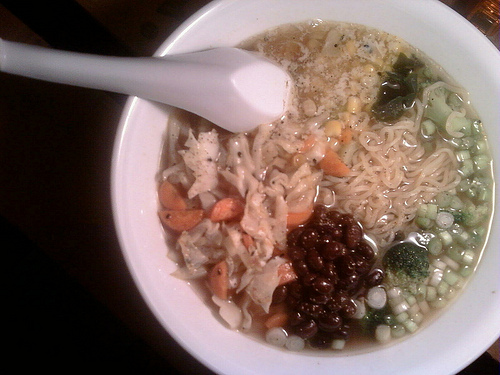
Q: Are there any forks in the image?
A: No, there are no forks.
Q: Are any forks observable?
A: No, there are no forks.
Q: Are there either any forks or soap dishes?
A: No, there are no forks or soap dishes.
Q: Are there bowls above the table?
A: Yes, there is a bowl above the table.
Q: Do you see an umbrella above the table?
A: No, there is a bowl above the table.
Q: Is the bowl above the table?
A: Yes, the bowl is above the table.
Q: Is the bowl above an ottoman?
A: No, the bowl is above the table.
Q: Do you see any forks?
A: No, there are no forks.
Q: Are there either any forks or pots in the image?
A: No, there are no forks or pots.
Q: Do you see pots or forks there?
A: No, there are no forks or pots.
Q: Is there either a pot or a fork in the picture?
A: No, there are no forks or pots.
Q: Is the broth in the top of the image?
A: Yes, the broth is in the top of the image.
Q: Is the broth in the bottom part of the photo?
A: No, the broth is in the top of the image.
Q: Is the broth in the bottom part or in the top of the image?
A: The broth is in the top of the image.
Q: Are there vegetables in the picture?
A: Yes, there are vegetables.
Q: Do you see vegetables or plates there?
A: Yes, there are vegetables.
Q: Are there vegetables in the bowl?
A: Yes, there are vegetables in the bowl.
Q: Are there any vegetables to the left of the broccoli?
A: Yes, there are vegetables to the left of the broccoli.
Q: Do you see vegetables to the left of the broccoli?
A: Yes, there are vegetables to the left of the broccoli.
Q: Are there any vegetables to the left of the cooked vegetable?
A: Yes, there are vegetables to the left of the broccoli.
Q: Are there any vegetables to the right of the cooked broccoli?
A: No, the vegetables are to the left of the broccoli.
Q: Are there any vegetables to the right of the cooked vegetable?
A: No, the vegetables are to the left of the broccoli.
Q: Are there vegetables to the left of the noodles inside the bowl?
A: Yes, there are vegetables to the left of the noodles.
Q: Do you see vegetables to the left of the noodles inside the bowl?
A: Yes, there are vegetables to the left of the noodles.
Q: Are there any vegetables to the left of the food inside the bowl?
A: Yes, there are vegetables to the left of the noodles.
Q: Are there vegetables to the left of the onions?
A: Yes, there are vegetables to the left of the onions.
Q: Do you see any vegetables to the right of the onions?
A: No, the vegetables are to the left of the onions.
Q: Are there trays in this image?
A: No, there are no trays.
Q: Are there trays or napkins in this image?
A: No, there are no trays or napkins.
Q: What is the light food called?
A: The food is Chinese food.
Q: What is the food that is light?
A: The food is Chinese food.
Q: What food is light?
A: The food is Chinese food.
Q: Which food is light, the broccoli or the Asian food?
A: The Asian food is light.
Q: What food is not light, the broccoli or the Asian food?
A: The broccoli is not light.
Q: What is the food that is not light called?
A: The food is broccoli.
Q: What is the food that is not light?
A: The food is broccoli.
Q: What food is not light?
A: The food is broccoli.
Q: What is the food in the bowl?
A: The food is Chinese food.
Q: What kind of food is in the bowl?
A: The food is Chinese food.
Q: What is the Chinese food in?
A: The Chinese food is in the bowl.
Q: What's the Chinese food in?
A: The Chinese food is in the bowl.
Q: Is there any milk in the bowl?
A: No, there is Chinese food in the bowl.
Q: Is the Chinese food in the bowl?
A: Yes, the Chinese food is in the bowl.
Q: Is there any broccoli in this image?
A: Yes, there is broccoli.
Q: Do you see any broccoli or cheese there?
A: Yes, there is broccoli.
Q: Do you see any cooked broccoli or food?
A: Yes, there is cooked broccoli.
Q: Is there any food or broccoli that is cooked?
A: Yes, the broccoli is cooked.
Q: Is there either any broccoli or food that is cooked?
A: Yes, the broccoli is cooked.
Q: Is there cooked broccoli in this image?
A: Yes, there is cooked broccoli.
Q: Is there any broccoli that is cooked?
A: Yes, there is broccoli that is cooked.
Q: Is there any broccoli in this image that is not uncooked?
A: Yes, there is cooked broccoli.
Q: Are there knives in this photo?
A: No, there are no knives.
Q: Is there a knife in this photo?
A: No, there are no knives.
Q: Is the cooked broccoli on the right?
A: Yes, the broccoli is on the right of the image.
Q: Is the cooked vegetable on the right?
A: Yes, the broccoli is on the right of the image.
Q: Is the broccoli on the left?
A: No, the broccoli is on the right of the image.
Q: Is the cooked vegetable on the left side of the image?
A: No, the broccoli is on the right of the image.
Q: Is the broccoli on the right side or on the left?
A: The broccoli is on the right of the image.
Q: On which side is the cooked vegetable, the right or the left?
A: The broccoli is on the right of the image.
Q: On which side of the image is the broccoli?
A: The broccoli is on the right of the image.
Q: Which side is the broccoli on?
A: The broccoli is on the right of the image.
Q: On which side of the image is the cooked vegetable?
A: The broccoli is on the right of the image.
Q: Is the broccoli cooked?
A: Yes, the broccoli is cooked.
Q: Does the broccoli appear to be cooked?
A: Yes, the broccoli is cooked.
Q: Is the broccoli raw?
A: No, the broccoli is cooked.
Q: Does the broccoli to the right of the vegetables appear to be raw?
A: No, the broccoli is cooked.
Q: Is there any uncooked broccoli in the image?
A: No, there is broccoli but it is cooked.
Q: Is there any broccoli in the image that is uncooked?
A: No, there is broccoli but it is cooked.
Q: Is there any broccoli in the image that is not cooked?
A: No, there is broccoli but it is cooked.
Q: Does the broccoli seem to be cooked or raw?
A: The broccoli is cooked.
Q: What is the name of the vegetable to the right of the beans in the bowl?
A: The vegetable is broccoli.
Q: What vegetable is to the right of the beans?
A: The vegetable is broccoli.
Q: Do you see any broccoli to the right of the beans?
A: Yes, there is broccoli to the right of the beans.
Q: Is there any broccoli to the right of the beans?
A: Yes, there is broccoli to the right of the beans.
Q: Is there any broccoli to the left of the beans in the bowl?
A: No, the broccoli is to the right of the beans.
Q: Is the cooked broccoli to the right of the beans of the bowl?
A: Yes, the broccoli is to the right of the beans.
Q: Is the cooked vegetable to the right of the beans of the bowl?
A: Yes, the broccoli is to the right of the beans.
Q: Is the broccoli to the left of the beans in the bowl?
A: No, the broccoli is to the right of the beans.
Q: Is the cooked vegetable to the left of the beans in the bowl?
A: No, the broccoli is to the right of the beans.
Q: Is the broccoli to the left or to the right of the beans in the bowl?
A: The broccoli is to the right of the beans.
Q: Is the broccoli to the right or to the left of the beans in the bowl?
A: The broccoli is to the right of the beans.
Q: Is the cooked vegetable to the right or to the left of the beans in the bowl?
A: The broccoli is to the right of the beans.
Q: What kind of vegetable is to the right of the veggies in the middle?
A: The vegetable is broccoli.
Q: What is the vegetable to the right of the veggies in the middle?
A: The vegetable is broccoli.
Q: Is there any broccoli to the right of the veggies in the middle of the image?
A: Yes, there is broccoli to the right of the vegetables.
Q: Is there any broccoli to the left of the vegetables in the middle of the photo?
A: No, the broccoli is to the right of the veggies.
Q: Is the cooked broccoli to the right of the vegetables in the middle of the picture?
A: Yes, the broccoli is to the right of the vegetables.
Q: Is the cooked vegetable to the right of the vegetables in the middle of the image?
A: Yes, the broccoli is to the right of the vegetables.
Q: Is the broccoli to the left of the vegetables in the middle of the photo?
A: No, the broccoli is to the right of the vegetables.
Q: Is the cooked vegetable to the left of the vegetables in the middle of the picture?
A: No, the broccoli is to the right of the vegetables.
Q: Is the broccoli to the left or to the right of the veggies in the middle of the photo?
A: The broccoli is to the right of the veggies.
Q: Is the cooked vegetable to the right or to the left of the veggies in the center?
A: The broccoli is to the right of the veggies.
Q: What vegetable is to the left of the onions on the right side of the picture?
A: The vegetable is broccoli.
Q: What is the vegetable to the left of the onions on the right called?
A: The vegetable is broccoli.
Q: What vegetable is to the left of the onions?
A: The vegetable is broccoli.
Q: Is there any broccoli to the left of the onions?
A: Yes, there is broccoli to the left of the onions.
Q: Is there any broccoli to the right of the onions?
A: No, the broccoli is to the left of the onions.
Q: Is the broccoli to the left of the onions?
A: Yes, the broccoli is to the left of the onions.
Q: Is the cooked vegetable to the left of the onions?
A: Yes, the broccoli is to the left of the onions.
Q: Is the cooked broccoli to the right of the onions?
A: No, the broccoli is to the left of the onions.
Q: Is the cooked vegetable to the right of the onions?
A: No, the broccoli is to the left of the onions.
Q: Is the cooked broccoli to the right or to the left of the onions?
A: The broccoli is to the left of the onions.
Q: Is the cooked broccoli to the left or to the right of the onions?
A: The broccoli is to the left of the onions.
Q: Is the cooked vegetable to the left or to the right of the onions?
A: The broccoli is to the left of the onions.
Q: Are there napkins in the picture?
A: No, there are no napkins.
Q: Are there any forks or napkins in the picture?
A: No, there are no napkins or forks.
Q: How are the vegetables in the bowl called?
A: The vegetables are beans.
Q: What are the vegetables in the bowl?
A: The vegetables are beans.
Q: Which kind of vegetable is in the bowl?
A: The vegetables are beans.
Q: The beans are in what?
A: The beans are in the bowl.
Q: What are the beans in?
A: The beans are in the bowl.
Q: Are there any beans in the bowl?
A: Yes, there are beans in the bowl.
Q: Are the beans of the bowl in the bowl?
A: Yes, the beans are in the bowl.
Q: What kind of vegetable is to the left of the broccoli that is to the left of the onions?
A: The vegetables are beans.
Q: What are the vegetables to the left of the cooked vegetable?
A: The vegetables are beans.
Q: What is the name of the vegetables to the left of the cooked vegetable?
A: The vegetables are beans.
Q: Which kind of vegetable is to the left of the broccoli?
A: The vegetables are beans.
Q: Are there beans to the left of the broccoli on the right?
A: Yes, there are beans to the left of the broccoli.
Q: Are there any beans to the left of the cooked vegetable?
A: Yes, there are beans to the left of the broccoli.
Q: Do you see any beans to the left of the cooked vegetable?
A: Yes, there are beans to the left of the broccoli.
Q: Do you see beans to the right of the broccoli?
A: No, the beans are to the left of the broccoli.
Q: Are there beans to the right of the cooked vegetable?
A: No, the beans are to the left of the broccoli.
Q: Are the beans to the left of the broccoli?
A: Yes, the beans are to the left of the broccoli.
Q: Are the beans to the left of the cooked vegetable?
A: Yes, the beans are to the left of the broccoli.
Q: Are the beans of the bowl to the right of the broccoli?
A: No, the beans are to the left of the broccoli.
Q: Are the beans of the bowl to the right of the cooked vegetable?
A: No, the beans are to the left of the broccoli.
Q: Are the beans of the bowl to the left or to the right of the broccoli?
A: The beans are to the left of the broccoli.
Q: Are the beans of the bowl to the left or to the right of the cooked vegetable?
A: The beans are to the left of the broccoli.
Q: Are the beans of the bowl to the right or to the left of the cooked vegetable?
A: The beans are to the left of the broccoli.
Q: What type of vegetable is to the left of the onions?
A: The vegetables are beans.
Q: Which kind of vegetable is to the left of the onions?
A: The vegetables are beans.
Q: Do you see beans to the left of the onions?
A: Yes, there are beans to the left of the onions.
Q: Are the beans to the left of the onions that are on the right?
A: Yes, the beans are to the left of the onions.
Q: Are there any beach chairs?
A: No, there are no beach chairs.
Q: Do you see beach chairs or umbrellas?
A: No, there are no beach chairs or umbrellas.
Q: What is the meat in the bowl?
A: The meat is chicken.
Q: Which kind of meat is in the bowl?
A: The meat is chicken.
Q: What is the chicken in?
A: The chicken is in the bowl.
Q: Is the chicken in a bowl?
A: Yes, the chicken is in a bowl.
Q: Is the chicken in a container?
A: No, the chicken is in a bowl.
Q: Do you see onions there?
A: Yes, there are onions.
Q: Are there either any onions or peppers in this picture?
A: Yes, there are onions.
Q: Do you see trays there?
A: No, there are no trays.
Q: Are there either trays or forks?
A: No, there are no trays or forks.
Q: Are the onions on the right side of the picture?
A: Yes, the onions are on the right of the image.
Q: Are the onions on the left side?
A: No, the onions are on the right of the image.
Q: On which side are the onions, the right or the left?
A: The onions are on the right of the image.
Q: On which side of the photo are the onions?
A: The onions are on the right of the image.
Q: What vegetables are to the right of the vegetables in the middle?
A: The vegetables are onions.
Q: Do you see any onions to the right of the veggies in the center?
A: Yes, there are onions to the right of the vegetables.